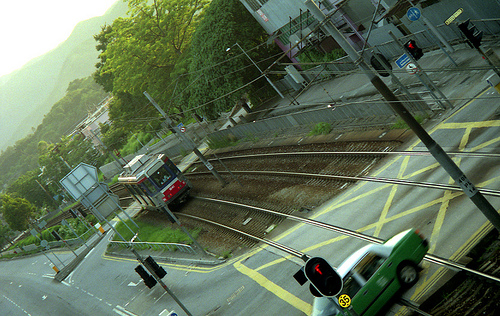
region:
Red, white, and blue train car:
[115, 150, 197, 215]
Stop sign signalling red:
[296, 262, 347, 300]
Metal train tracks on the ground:
[218, 149, 353, 255]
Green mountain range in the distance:
[4, 52, 82, 159]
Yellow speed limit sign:
[334, 287, 354, 309]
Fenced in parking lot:
[234, 29, 479, 123]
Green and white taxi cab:
[291, 224, 450, 313]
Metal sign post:
[81, 227, 204, 314]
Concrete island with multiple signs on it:
[47, 222, 122, 282]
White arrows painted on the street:
[6, 278, 73, 311]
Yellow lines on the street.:
[98, 118, 498, 313]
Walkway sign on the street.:
[288, 251, 348, 297]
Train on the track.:
[109, 149, 186, 219]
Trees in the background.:
[3, 5, 303, 250]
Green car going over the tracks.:
[301, 226, 430, 313]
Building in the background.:
[242, 1, 481, 104]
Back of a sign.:
[54, 159, 136, 233]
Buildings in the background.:
[76, 3, 494, 148]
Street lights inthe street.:
[123, 236, 201, 313]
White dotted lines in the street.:
[3, 255, 133, 313]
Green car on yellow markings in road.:
[326, 245, 415, 306]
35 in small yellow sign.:
[331, 288, 349, 312]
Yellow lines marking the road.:
[296, 231, 484, 240]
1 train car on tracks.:
[108, 132, 244, 235]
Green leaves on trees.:
[99, 62, 216, 126]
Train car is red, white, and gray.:
[140, 142, 208, 230]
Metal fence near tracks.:
[285, 112, 452, 152]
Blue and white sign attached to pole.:
[393, 13, 437, 32]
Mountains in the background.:
[18, 33, 180, 138]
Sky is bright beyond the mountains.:
[4, 21, 74, 63]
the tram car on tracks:
[65, 110, 232, 231]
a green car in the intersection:
[260, 194, 418, 299]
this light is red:
[384, 32, 454, 91]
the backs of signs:
[21, 140, 138, 249]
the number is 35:
[313, 276, 375, 312]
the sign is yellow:
[305, 264, 382, 314]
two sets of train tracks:
[213, 110, 493, 277]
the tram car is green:
[72, 113, 246, 231]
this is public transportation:
[91, 136, 239, 226]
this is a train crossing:
[21, 55, 496, 277]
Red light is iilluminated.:
[303, 256, 345, 289]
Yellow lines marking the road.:
[357, 165, 463, 255]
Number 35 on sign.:
[331, 297, 361, 314]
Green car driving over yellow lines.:
[311, 270, 433, 314]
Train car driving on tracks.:
[146, 157, 255, 244]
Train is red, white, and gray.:
[139, 155, 210, 220]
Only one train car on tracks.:
[109, 145, 224, 212]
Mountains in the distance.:
[29, 46, 142, 118]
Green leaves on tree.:
[132, 55, 224, 102]